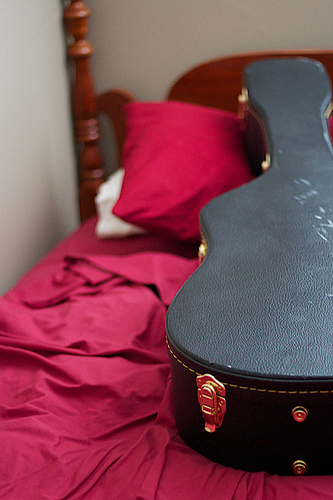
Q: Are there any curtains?
A: No, there are no curtains.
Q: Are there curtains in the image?
A: No, there are no curtains.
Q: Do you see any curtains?
A: No, there are no curtains.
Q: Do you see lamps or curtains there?
A: No, there are no curtains or lamps.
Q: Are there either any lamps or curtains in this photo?
A: No, there are no curtains or lamps.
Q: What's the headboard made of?
A: The headboard is made of wood.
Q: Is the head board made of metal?
A: No, the head board is made of wood.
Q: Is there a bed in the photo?
A: Yes, there is a bed.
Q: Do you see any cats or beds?
A: Yes, there is a bed.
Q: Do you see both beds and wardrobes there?
A: No, there is a bed but no wardrobes.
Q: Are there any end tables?
A: No, there are no end tables.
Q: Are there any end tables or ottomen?
A: No, there are no end tables or ottomen.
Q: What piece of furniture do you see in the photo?
A: The piece of furniture is a bed.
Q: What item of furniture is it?
A: The piece of furniture is a bed.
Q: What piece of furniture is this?
A: This is a bed.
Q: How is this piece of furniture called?
A: This is a bed.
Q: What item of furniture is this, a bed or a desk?
A: This is a bed.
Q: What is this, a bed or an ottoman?
A: This is a bed.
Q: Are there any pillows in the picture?
A: Yes, there is a pillow.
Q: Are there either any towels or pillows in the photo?
A: Yes, there is a pillow.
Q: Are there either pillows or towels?
A: Yes, there is a pillow.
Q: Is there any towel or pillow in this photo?
A: Yes, there is a pillow.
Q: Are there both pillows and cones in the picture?
A: No, there is a pillow but no cones.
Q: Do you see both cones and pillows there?
A: No, there is a pillow but no cones.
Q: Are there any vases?
A: No, there are no vases.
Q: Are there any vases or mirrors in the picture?
A: No, there are no vases or mirrors.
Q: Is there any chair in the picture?
A: No, there are no chairs.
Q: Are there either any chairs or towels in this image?
A: No, there are no chairs or towels.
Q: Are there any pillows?
A: Yes, there is a pillow.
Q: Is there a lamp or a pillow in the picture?
A: Yes, there is a pillow.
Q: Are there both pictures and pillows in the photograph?
A: No, there is a pillow but no pictures.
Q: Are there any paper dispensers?
A: No, there are no paper dispensers.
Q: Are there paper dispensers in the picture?
A: No, there are no paper dispensers.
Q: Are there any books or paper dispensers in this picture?
A: No, there are no paper dispensers or books.